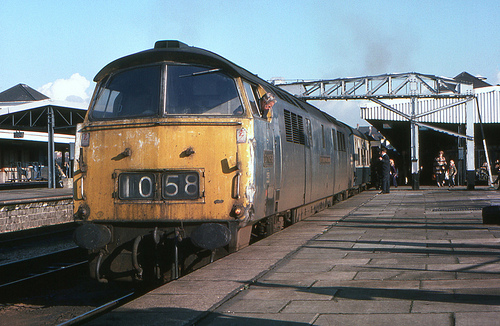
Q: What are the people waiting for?
A: Board the train.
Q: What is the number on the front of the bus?
A: 1058.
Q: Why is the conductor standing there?
A: Checking tickets.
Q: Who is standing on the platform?
A: Conductor.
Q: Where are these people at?
A: Train station.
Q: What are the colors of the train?
A: Yellow and silver.